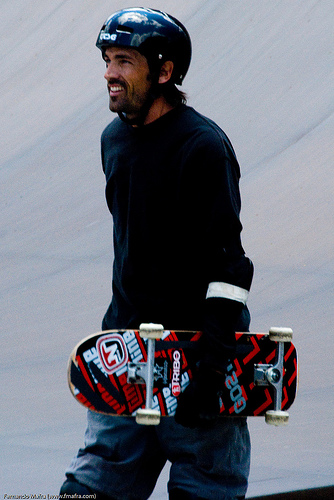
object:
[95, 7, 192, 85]
helmet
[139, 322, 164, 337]
wheel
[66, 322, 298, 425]
skateboard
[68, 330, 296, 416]
colors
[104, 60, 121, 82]
nose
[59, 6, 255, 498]
man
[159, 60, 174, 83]
ear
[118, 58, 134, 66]
eye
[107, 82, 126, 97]
mouth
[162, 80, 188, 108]
hair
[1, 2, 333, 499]
half pipe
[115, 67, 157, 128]
strap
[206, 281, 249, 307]
stripe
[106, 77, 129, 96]
mustache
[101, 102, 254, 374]
shirt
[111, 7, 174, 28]
light reflecting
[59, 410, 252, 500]
jeans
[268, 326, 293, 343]
wheels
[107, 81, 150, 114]
beard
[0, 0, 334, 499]
photo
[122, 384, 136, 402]
words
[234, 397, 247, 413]
words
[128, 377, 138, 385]
screw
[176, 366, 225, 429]
gloves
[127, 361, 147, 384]
bracket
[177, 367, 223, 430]
hand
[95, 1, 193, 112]
head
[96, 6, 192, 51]
shine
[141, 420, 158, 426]
white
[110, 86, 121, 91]
white teeth